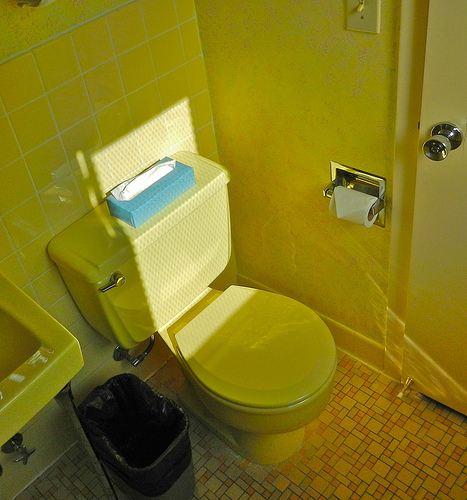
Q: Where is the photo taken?
A: Bathroom.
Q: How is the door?
A: Ajar.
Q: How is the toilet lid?
A: Down.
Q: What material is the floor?
A: Tiles.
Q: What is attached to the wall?
A: Toilet paper dispenser.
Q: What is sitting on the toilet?
A: Tissue.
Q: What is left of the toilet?
A: A sink.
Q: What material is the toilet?
A: Porcelain.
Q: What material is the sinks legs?
A: Metal.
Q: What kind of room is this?
A: Bathroom.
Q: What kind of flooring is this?
A: Tile.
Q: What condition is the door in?
A: Closed.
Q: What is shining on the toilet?
A: Sunlight.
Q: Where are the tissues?
A: Top of toilet tank.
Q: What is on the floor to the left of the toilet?
A: Trash can.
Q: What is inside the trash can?
A: Trash bag.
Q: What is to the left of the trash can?
A: Sink.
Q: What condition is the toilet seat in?
A: Closed and down.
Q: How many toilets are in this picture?
A: 1.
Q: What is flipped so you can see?
A: Light switch.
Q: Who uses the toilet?
A: People.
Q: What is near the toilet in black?
A: Trashcan.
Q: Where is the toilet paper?
A: To the right.